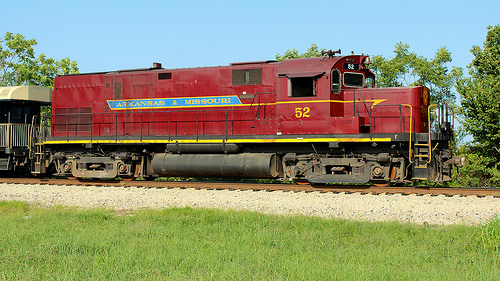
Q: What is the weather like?
A: It is clear.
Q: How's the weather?
A: It is clear.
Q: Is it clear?
A: Yes, it is clear.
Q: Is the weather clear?
A: Yes, it is clear.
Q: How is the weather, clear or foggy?
A: It is clear.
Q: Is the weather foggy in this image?
A: No, it is clear.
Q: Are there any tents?
A: No, there are no tents.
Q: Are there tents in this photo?
A: No, there are no tents.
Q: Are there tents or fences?
A: No, there are no tents or fences.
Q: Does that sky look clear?
A: Yes, the sky is clear.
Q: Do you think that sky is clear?
A: Yes, the sky is clear.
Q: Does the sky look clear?
A: Yes, the sky is clear.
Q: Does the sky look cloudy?
A: No, the sky is clear.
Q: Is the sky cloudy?
A: No, the sky is clear.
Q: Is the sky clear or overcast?
A: The sky is clear.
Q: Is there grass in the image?
A: Yes, there is grass.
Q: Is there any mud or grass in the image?
A: Yes, there is grass.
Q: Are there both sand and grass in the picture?
A: No, there is grass but no sand.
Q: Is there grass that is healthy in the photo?
A: Yes, there is healthy grass.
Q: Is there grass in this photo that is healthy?
A: Yes, there is grass that is healthy.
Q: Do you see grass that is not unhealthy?
A: Yes, there is healthy grass.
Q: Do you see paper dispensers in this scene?
A: No, there are no paper dispensers.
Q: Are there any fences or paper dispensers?
A: No, there are no paper dispensers or fences.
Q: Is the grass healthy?
A: Yes, the grass is healthy.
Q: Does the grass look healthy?
A: Yes, the grass is healthy.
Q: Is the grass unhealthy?
A: No, the grass is healthy.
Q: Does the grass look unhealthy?
A: No, the grass is healthy.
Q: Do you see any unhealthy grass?
A: No, there is grass but it is healthy.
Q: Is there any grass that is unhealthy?
A: No, there is grass but it is healthy.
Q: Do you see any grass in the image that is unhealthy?
A: No, there is grass but it is healthy.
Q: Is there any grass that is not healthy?
A: No, there is grass but it is healthy.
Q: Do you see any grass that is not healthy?
A: No, there is grass but it is healthy.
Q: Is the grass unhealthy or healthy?
A: The grass is healthy.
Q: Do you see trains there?
A: Yes, there is a train.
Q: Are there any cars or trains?
A: Yes, there is a train.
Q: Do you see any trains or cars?
A: Yes, there is a train.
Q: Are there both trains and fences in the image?
A: No, there is a train but no fences.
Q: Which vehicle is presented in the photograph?
A: The vehicle is a train.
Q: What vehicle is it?
A: The vehicle is a train.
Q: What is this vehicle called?
A: This is a train.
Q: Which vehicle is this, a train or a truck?
A: This is a train.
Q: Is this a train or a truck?
A: This is a train.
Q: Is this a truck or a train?
A: This is a train.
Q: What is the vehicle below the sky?
A: The vehicle is a train.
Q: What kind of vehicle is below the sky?
A: The vehicle is a train.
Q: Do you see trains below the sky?
A: Yes, there is a train below the sky.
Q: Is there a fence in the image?
A: No, there are no fences.